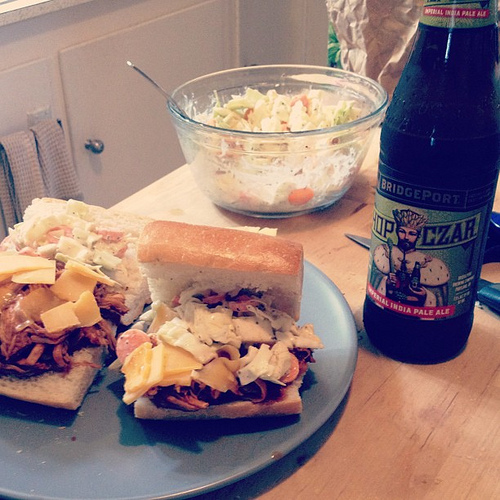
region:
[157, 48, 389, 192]
salad is in a bowl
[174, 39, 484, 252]
the glass bowl is on the counter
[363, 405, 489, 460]
the counter is made of wood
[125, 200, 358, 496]
a sandwich is on a plate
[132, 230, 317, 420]
the sandwich is cut in half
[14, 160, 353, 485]
the plate is blue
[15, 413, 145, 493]
crumbs are on the plate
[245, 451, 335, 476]
sauce is on the plate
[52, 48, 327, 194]
the cabinet are white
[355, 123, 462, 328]
a beer is on the table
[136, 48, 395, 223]
A homemade bowl of ingredients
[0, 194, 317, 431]
A sandwich on bread with meat and cheese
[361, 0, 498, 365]
A dark bottle of pale ale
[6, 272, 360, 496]
A pale blue dinner plate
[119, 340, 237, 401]
Sliced cheddar cheese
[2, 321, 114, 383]
Pulled meat in a sandwich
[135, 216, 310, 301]
Half of a slice of white sandwich bread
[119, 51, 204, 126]
The end of a serving utensil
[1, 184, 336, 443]
A homemade pulled pork and cheese sandwich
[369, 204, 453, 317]
An image of royalty holding pale beer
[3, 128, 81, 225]
Plaid dish towels hanging from the cabinet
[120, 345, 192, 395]
Orange cheese slices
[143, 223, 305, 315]
Tan bread crust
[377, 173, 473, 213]
Beer manufactured in Bridgeport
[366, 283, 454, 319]
Imperial India Pale Ale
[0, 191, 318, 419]
Two open faced sandwiches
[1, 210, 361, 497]
Blue plate containing two sandwiches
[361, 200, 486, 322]
Hop Czar beer label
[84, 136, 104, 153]
Silver knob to cabinet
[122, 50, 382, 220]
Utensil sticking out of salad bowl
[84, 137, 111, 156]
small silver door knob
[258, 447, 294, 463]
tiny brown spot on plate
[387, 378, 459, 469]
light pink color on table top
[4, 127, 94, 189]
kitchen towel on the rack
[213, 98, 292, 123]
cole slaw in the bowl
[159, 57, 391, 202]
large clear bowl on table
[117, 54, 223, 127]
large spoon in the bowl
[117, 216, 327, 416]
half of sandwich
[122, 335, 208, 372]
white cheese slices on sandwich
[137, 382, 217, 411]
pieces of brown meat on sandwich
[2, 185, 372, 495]
the sandwich on the plate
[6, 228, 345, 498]
the plate is round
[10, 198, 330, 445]
the sandwich cut in half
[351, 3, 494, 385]
the bottle of ale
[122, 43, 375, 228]
the potato salad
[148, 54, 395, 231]
the bowl is clear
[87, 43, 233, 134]
the spoon in the bowl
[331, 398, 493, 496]
the table is wooden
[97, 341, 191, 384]
cheese in the sandwich